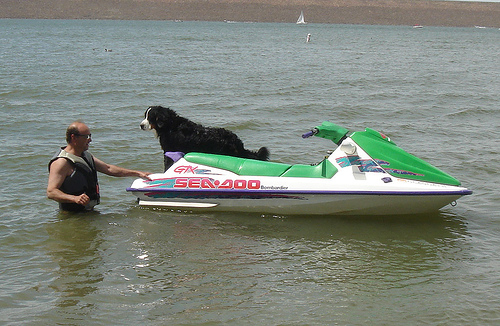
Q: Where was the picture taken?
A: It was taken at the lake.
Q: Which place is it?
A: It is a lake.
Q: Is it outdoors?
A: Yes, it is outdoors.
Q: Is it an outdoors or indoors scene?
A: It is outdoors.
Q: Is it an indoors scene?
A: No, it is outdoors.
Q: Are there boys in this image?
A: No, there are no boys.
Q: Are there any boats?
A: Yes, there is a boat.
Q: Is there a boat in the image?
A: Yes, there is a boat.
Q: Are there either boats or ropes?
A: Yes, there is a boat.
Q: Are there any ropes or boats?
A: Yes, there is a boat.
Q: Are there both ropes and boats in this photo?
A: No, there is a boat but no ropes.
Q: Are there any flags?
A: No, there are no flags.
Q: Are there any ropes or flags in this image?
A: No, there are no flags or ropes.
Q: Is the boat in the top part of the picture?
A: Yes, the boat is in the top of the image.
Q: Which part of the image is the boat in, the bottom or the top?
A: The boat is in the top of the image.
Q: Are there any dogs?
A: Yes, there is a dog.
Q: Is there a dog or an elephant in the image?
A: Yes, there is a dog.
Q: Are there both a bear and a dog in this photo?
A: No, there is a dog but no bears.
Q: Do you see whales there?
A: No, there are no whales.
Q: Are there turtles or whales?
A: No, there are no whales or turtles.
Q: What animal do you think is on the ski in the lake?
A: The dog is on the ski.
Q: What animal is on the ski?
A: The dog is on the ski.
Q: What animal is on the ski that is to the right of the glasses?
A: The animal is a dog.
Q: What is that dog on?
A: The dog is on the ski.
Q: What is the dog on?
A: The dog is on the ski.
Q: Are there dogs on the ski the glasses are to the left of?
A: Yes, there is a dog on the ski.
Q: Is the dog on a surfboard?
A: No, the dog is on the ski.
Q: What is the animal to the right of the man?
A: The animal is a dog.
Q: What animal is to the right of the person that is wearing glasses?
A: The animal is a dog.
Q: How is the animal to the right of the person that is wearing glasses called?
A: The animal is a dog.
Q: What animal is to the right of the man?
A: The animal is a dog.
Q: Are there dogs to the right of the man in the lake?
A: Yes, there is a dog to the right of the man.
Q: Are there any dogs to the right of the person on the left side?
A: Yes, there is a dog to the right of the man.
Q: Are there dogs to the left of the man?
A: No, the dog is to the right of the man.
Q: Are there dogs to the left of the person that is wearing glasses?
A: No, the dog is to the right of the man.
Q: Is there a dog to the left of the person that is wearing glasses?
A: No, the dog is to the right of the man.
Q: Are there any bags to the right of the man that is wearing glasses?
A: No, there is a dog to the right of the man.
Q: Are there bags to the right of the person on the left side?
A: No, there is a dog to the right of the man.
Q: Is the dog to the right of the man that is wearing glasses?
A: Yes, the dog is to the right of the man.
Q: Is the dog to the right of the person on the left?
A: Yes, the dog is to the right of the man.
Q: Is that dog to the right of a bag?
A: No, the dog is to the right of the man.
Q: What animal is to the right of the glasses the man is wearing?
A: The animal is a dog.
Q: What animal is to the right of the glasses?
A: The animal is a dog.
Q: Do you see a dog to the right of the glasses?
A: Yes, there is a dog to the right of the glasses.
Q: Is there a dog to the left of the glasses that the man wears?
A: No, the dog is to the right of the glasses.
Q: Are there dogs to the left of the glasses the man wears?
A: No, the dog is to the right of the glasses.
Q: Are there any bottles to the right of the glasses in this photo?
A: No, there is a dog to the right of the glasses.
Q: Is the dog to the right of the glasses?
A: Yes, the dog is to the right of the glasses.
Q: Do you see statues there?
A: No, there are no statues.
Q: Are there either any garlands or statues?
A: No, there are no statues or garlands.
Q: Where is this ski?
A: The ski is in the lake.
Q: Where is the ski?
A: The ski is in the lake.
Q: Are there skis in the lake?
A: Yes, there is a ski in the lake.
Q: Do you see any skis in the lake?
A: Yes, there is a ski in the lake.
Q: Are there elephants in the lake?
A: No, there is a ski in the lake.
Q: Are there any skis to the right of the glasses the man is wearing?
A: Yes, there is a ski to the right of the glasses.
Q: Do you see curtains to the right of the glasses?
A: No, there is a ski to the right of the glasses.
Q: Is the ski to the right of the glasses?
A: Yes, the ski is to the right of the glasses.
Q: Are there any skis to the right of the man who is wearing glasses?
A: Yes, there is a ski to the right of the man.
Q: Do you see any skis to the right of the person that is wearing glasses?
A: Yes, there is a ski to the right of the man.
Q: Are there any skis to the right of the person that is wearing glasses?
A: Yes, there is a ski to the right of the man.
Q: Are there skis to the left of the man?
A: No, the ski is to the right of the man.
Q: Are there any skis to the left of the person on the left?
A: No, the ski is to the right of the man.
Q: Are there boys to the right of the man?
A: No, there is a ski to the right of the man.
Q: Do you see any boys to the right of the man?
A: No, there is a ski to the right of the man.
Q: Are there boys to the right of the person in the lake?
A: No, there is a ski to the right of the man.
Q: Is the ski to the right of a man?
A: Yes, the ski is to the right of a man.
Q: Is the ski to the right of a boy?
A: No, the ski is to the right of a man.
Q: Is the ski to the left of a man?
A: No, the ski is to the right of a man.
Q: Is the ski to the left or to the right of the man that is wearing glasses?
A: The ski is to the right of the man.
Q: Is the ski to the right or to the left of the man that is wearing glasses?
A: The ski is to the right of the man.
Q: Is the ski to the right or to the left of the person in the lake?
A: The ski is to the right of the man.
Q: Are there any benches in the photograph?
A: No, there are no benches.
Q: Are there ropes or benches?
A: No, there are no benches or ropes.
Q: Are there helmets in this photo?
A: No, there are no helmets.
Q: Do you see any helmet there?
A: No, there are no helmets.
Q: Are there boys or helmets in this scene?
A: No, there are no helmets or boys.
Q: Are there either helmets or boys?
A: No, there are no helmets or boys.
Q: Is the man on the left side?
A: Yes, the man is on the left of the image.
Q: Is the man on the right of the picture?
A: No, the man is on the left of the image.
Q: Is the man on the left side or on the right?
A: The man is on the left of the image.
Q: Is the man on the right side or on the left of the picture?
A: The man is on the left of the image.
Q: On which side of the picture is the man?
A: The man is on the left of the image.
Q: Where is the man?
A: The man is in the lake.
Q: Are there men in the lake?
A: Yes, there is a man in the lake.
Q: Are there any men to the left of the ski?
A: Yes, there is a man to the left of the ski.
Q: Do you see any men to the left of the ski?
A: Yes, there is a man to the left of the ski.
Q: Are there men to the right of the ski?
A: No, the man is to the left of the ski.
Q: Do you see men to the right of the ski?
A: No, the man is to the left of the ski.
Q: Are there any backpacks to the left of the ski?
A: No, there is a man to the left of the ski.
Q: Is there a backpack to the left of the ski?
A: No, there is a man to the left of the ski.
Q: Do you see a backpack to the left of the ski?
A: No, there is a man to the left of the ski.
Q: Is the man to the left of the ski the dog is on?
A: Yes, the man is to the left of the ski.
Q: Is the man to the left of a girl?
A: No, the man is to the left of the ski.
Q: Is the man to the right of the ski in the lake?
A: No, the man is to the left of the ski.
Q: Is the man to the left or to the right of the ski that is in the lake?
A: The man is to the left of the ski.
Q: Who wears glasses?
A: The man wears glasses.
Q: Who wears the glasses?
A: The man wears glasses.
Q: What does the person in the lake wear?
A: The man wears glasses.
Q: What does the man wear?
A: The man wears glasses.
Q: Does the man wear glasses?
A: Yes, the man wears glasses.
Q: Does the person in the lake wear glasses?
A: Yes, the man wears glasses.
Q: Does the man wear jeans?
A: No, the man wears glasses.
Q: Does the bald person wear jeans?
A: No, the man wears glasses.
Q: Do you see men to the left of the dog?
A: Yes, there is a man to the left of the dog.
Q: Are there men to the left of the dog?
A: Yes, there is a man to the left of the dog.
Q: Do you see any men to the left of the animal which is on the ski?
A: Yes, there is a man to the left of the dog.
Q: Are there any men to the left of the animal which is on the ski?
A: Yes, there is a man to the left of the dog.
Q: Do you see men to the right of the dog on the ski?
A: No, the man is to the left of the dog.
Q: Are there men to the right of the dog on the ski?
A: No, the man is to the left of the dog.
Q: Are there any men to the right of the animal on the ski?
A: No, the man is to the left of the dog.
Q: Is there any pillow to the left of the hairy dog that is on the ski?
A: No, there is a man to the left of the dog.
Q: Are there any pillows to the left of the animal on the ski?
A: No, there is a man to the left of the dog.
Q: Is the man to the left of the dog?
A: Yes, the man is to the left of the dog.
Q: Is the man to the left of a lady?
A: No, the man is to the left of the dog.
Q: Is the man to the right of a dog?
A: No, the man is to the left of a dog.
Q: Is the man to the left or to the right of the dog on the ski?
A: The man is to the left of the dog.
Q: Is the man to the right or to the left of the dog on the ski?
A: The man is to the left of the dog.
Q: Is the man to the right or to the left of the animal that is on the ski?
A: The man is to the left of the dog.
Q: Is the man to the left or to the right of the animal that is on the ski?
A: The man is to the left of the dog.